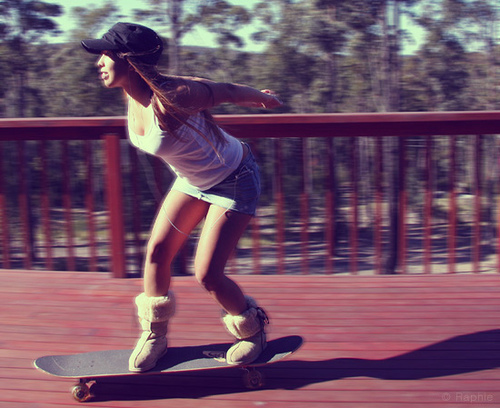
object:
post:
[12, 136, 34, 266]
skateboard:
[24, 329, 309, 399]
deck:
[0, 266, 500, 408]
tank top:
[119, 100, 251, 194]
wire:
[162, 214, 190, 238]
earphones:
[117, 52, 131, 64]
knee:
[198, 263, 222, 295]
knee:
[145, 237, 172, 264]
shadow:
[85, 323, 497, 400]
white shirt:
[129, 114, 249, 179]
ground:
[0, 186, 500, 271]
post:
[469, 132, 492, 271]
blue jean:
[170, 139, 265, 220]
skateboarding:
[19, 18, 324, 408]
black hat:
[76, 22, 172, 69]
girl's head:
[91, 36, 149, 86]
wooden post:
[58, 139, 76, 271]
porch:
[2, 265, 497, 406]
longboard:
[28, 326, 312, 398]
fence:
[274, 124, 500, 274]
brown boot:
[219, 297, 271, 364]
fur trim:
[219, 296, 270, 341]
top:
[129, 76, 226, 183]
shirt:
[119, 78, 250, 193]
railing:
[2, 113, 495, 279]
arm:
[164, 77, 266, 115]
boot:
[123, 292, 180, 373]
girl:
[94, 17, 280, 373]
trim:
[134, 294, 175, 324]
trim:
[215, 300, 270, 337]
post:
[343, 142, 363, 279]